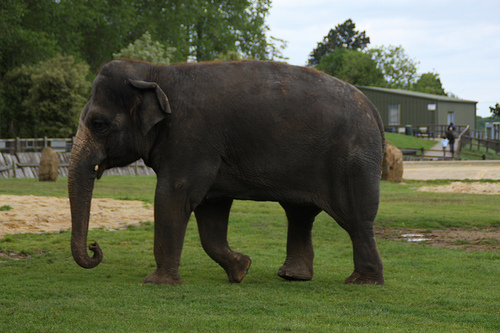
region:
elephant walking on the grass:
[62, 55, 397, 298]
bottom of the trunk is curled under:
[60, 145, 110, 272]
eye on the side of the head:
[91, 118, 103, 128]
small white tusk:
[91, 163, 100, 170]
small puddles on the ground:
[401, 229, 428, 244]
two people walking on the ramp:
[437, 118, 459, 161]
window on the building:
[385, 100, 405, 130]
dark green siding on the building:
[342, 80, 487, 141]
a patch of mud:
[370, 217, 495, 259]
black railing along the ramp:
[416, 123, 476, 158]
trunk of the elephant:
[54, 156, 118, 278]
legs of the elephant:
[114, 189, 406, 312]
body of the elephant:
[176, 72, 333, 188]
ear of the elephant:
[119, 69, 185, 141]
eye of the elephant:
[71, 99, 123, 157]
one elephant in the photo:
[23, 62, 424, 306]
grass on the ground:
[200, 285, 295, 331]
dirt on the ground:
[0, 184, 60, 239]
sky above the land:
[421, 16, 484, 56]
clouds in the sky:
[423, 5, 490, 60]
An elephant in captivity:
[53, 48, 406, 298]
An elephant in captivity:
[60, 50, 400, 300]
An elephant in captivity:
[57, 53, 400, 295]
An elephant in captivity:
[63, 49, 392, 296]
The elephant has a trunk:
[55, 88, 145, 288]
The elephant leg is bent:
[168, 145, 271, 297]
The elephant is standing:
[46, 42, 417, 302]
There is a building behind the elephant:
[342, 66, 489, 173]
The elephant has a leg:
[131, 136, 219, 294]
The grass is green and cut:
[8, 263, 498, 331]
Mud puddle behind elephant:
[385, 209, 498, 269]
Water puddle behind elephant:
[396, 215, 441, 254]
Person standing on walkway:
[439, 110, 472, 160]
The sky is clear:
[278, 0, 499, 60]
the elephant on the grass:
[47, 39, 415, 301]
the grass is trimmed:
[20, 263, 490, 325]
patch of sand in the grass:
[393, 218, 495, 258]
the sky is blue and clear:
[401, 6, 496, 61]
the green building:
[360, 76, 496, 133]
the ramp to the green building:
[424, 127, 463, 158]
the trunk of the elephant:
[58, 161, 118, 271]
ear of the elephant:
[118, 71, 179, 170]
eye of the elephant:
[80, 118, 122, 141]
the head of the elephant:
[65, 50, 165, 267]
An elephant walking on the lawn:
[63, 49, 391, 291]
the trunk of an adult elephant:
[65, 116, 107, 271]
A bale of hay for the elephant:
[384, 138, 406, 187]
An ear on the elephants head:
[102, 53, 174, 150]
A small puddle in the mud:
[392, 220, 435, 250]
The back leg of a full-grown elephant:
[325, 197, 392, 292]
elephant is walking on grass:
[68, 57, 388, 287]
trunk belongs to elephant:
[68, 121, 103, 267]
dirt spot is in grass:
[376, 220, 498, 254]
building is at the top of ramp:
[353, 84, 478, 137]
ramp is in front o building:
[388, 122, 498, 164]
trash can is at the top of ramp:
[406, 123, 414, 136]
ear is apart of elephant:
[130, 77, 172, 135]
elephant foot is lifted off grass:
[224, 250, 252, 282]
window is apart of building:
[386, 105, 400, 128]